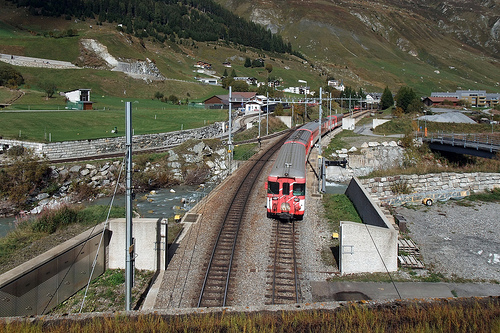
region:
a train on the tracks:
[244, 94, 386, 329]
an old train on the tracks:
[235, 75, 400, 278]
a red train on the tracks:
[228, 78, 325, 267]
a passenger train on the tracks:
[259, 77, 323, 257]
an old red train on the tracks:
[223, 103, 356, 290]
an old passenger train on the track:
[256, 95, 324, 261]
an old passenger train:
[255, 77, 353, 236]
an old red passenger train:
[255, 87, 371, 247]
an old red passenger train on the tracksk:
[244, 93, 361, 271]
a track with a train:
[218, 71, 379, 268]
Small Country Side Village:
[186, 58, 498, 108]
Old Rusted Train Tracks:
[169, 106, 377, 312]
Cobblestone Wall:
[0, 114, 243, 164]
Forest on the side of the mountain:
[10, 3, 302, 58]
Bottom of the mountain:
[0, 5, 497, 87]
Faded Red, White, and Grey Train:
[265, 115, 340, 225]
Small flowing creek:
[0, 172, 230, 236]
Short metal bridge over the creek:
[415, 128, 498, 165]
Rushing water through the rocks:
[129, 183, 208, 223]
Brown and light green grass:
[0, 300, 495, 332]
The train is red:
[248, 168, 308, 238]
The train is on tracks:
[256, 122, 336, 302]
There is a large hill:
[16, 23, 383, 179]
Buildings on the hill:
[67, 63, 379, 130]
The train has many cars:
[269, 105, 347, 221]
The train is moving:
[260, 98, 351, 230]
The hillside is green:
[35, 68, 143, 138]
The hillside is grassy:
[8, 38, 285, 156]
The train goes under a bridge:
[264, 145, 331, 330]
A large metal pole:
[110, 95, 136, 301]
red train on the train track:
[269, 127, 306, 228]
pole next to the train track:
[107, 104, 146, 322]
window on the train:
[290, 183, 308, 206]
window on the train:
[266, 174, 279, 199]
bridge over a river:
[412, 118, 493, 183]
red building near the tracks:
[202, 83, 258, 109]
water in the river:
[150, 186, 184, 216]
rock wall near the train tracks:
[385, 171, 477, 203]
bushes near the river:
[8, 155, 51, 205]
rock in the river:
[162, 184, 181, 202]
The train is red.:
[263, 112, 343, 218]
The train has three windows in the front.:
[266, 178, 307, 198]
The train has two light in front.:
[270, 193, 302, 202]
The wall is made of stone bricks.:
[357, 170, 499, 202]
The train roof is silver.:
[268, 112, 344, 178]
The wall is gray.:
[335, 175, 399, 275]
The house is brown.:
[203, 90, 258, 105]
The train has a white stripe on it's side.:
[263, 113, 343, 217]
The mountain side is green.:
[1, 1, 498, 142]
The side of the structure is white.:
[63, 86, 89, 102]